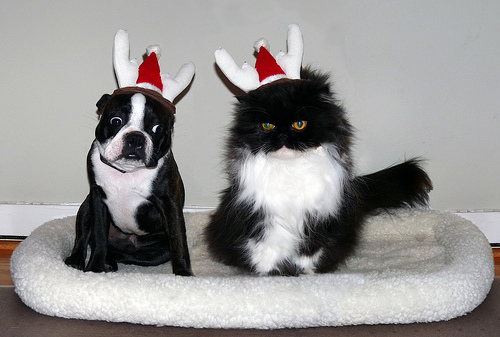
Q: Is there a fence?
A: No, there are no fences.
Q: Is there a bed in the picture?
A: Yes, there is a bed.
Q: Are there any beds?
A: Yes, there is a bed.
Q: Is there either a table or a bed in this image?
A: Yes, there is a bed.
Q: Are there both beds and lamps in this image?
A: No, there is a bed but no lamps.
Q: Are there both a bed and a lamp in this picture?
A: No, there is a bed but no lamps.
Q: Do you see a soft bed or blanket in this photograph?
A: Yes, there is a soft bed.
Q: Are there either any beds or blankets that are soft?
A: Yes, the bed is soft.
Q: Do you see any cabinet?
A: No, there are no cabinets.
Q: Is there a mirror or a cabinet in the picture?
A: No, there are no cabinets or mirrors.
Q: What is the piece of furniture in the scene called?
A: The piece of furniture is a bed.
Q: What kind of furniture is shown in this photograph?
A: The furniture is a bed.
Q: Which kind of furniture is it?
A: The piece of furniture is a bed.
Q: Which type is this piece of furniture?
A: This is a bed.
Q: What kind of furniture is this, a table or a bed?
A: This is a bed.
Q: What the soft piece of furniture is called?
A: The piece of furniture is a bed.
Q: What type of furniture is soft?
A: The furniture is a bed.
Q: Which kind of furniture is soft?
A: The furniture is a bed.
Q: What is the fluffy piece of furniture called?
A: The piece of furniture is a bed.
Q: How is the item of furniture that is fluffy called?
A: The piece of furniture is a bed.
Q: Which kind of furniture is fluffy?
A: The furniture is a bed.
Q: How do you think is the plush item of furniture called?
A: The piece of furniture is a bed.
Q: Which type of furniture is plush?
A: The furniture is a bed.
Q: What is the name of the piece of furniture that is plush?
A: The piece of furniture is a bed.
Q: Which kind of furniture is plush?
A: The furniture is a bed.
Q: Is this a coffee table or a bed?
A: This is a bed.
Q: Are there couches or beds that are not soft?
A: No, there is a bed but it is soft.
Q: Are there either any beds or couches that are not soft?
A: No, there is a bed but it is soft.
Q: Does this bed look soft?
A: Yes, the bed is soft.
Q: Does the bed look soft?
A: Yes, the bed is soft.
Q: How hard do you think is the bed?
A: The bed is soft.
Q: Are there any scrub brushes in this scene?
A: No, there are no scrub brushes.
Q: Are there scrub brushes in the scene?
A: No, there are no scrub brushes.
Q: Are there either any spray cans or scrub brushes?
A: No, there are no scrub brushes or spray cans.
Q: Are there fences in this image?
A: No, there are no fences.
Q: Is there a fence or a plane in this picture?
A: No, there are no fences or airplanes.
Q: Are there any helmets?
A: No, there are no helmets.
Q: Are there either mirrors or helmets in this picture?
A: No, there are no helmets or mirrors.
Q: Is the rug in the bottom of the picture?
A: Yes, the rug is in the bottom of the image.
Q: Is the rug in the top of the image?
A: No, the rug is in the bottom of the image.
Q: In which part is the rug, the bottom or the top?
A: The rug is in the bottom of the image.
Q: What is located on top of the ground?
A: The rug is on top of the ground.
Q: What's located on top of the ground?
A: The rug is on top of the ground.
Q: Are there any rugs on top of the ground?
A: Yes, there is a rug on top of the ground.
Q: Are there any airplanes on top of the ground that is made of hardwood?
A: No, there is a rug on top of the ground.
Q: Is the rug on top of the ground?
A: Yes, the rug is on top of the ground.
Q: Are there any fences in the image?
A: No, there are no fences.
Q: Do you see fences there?
A: No, there are no fences.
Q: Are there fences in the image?
A: No, there are no fences.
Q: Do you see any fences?
A: No, there are no fences.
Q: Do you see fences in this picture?
A: No, there are no fences.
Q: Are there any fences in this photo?
A: No, there are no fences.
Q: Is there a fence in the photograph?
A: No, there are no fences.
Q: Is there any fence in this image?
A: No, there are no fences.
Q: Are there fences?
A: No, there are no fences.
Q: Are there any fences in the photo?
A: No, there are no fences.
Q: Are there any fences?
A: No, there are no fences.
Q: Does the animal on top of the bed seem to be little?
A: Yes, the animal is little.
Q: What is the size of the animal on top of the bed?
A: The animal is little.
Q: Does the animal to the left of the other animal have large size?
A: No, the animal is little.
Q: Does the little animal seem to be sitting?
A: Yes, the animal is sitting.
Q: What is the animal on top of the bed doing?
A: The animal is sitting.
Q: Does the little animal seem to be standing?
A: No, the animal is sitting.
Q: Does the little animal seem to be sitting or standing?
A: The animal is sitting.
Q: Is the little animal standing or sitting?
A: The animal is sitting.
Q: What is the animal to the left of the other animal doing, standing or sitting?
A: The animal is sitting.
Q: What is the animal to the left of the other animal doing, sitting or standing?
A: The animal is sitting.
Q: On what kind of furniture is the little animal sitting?
A: The animal is sitting on the bed.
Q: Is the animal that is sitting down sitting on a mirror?
A: No, the animal is sitting on the bed.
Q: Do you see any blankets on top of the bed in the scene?
A: No, there is an animal on top of the bed.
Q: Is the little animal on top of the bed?
A: Yes, the animal is on top of the bed.